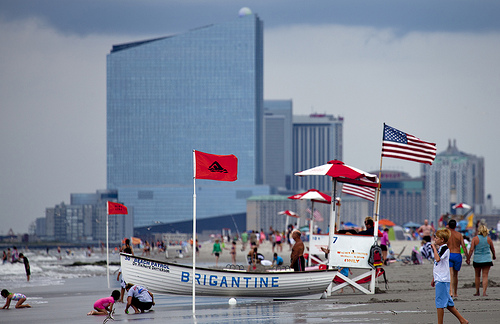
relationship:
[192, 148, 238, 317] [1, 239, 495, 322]
flag in sand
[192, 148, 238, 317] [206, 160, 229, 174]
flag has logo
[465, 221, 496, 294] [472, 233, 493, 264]
woman wearing tank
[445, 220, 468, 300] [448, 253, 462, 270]
man wearing shorts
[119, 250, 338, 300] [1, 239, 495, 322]
boat on sand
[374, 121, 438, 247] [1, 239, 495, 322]
flag in sand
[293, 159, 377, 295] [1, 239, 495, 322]
umbrella in sand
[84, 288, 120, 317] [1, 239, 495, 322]
girl on sand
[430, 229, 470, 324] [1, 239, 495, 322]
boy on sand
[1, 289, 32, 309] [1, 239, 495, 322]
girl in sand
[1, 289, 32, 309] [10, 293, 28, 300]
girl wearing bathing suit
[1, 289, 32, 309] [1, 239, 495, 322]
girl playing on sand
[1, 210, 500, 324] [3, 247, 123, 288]
people in water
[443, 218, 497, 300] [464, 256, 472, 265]
couple holding hands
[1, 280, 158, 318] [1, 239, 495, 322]
children playing on sand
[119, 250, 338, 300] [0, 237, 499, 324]
boat on beach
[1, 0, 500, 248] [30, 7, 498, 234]
city has buildings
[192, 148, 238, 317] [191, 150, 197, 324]
flag on pole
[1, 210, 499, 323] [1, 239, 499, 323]
people on beach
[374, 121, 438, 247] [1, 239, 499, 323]
flag on beach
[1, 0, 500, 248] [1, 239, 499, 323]
city on beach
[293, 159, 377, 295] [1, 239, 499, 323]
umbrella on beach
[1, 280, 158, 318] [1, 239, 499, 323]
children playing on beach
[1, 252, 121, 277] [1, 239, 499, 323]
waves on beach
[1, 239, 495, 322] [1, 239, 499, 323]
sand on beach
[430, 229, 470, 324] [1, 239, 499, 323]
boy on beach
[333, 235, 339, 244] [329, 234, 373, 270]
number on sign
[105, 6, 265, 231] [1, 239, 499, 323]
building near beach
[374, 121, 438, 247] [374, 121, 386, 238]
flag on pole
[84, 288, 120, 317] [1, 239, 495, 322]
girl playing in sand